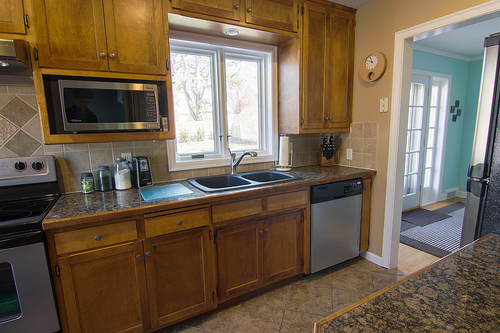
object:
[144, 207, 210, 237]
drawer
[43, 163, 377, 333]
counter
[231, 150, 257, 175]
faucet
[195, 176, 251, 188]
sink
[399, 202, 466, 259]
mat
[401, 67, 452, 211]
door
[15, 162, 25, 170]
knobs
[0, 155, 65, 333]
stove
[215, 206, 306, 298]
cabinets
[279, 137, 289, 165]
towels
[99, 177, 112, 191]
spices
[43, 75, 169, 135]
microwave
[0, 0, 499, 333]
kitchen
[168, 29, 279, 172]
window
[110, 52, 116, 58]
knobs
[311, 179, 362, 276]
dishwasher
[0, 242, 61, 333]
oven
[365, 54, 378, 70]
clock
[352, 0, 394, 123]
wall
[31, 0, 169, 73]
cabinets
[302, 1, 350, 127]
cabinets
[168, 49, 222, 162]
sunlight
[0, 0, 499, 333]
daytime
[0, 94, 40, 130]
tile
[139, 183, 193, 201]
board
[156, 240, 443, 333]
floor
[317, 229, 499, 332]
counter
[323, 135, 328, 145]
knives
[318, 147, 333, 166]
block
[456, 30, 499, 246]
refrigerator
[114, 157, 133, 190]
jar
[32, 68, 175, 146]
shelf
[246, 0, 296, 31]
cabinet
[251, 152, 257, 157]
tap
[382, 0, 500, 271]
door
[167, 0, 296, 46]
shelves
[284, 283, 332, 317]
tile